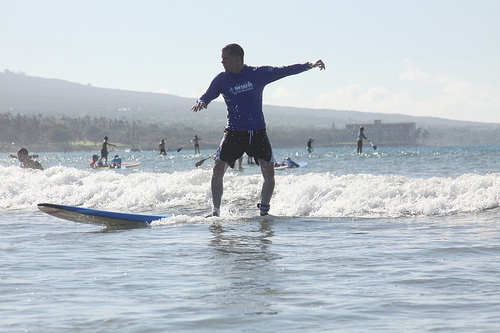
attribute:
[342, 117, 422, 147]
building — large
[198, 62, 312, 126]
shirt — blue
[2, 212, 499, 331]
water — blue, rippled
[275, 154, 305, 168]
person — sitting down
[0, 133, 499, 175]
water — blue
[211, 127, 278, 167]
shorts — black-and-white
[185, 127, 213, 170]
person — standing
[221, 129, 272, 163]
shorts — black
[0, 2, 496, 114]
sky — blue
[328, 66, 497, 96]
cloud — white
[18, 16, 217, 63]
cloud — white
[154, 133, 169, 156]
person — standing up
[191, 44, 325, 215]
person — standing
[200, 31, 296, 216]
person — standing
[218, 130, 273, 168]
shorts — black 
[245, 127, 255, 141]
tie string — white